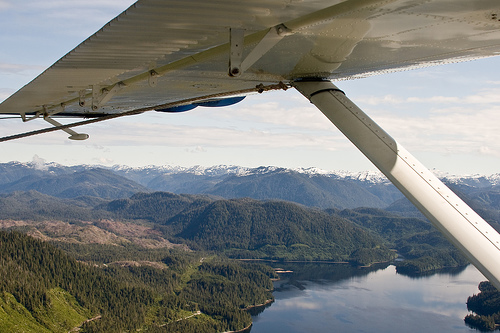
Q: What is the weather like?
A: It is clear.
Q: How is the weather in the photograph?
A: It is clear.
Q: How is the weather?
A: It is clear.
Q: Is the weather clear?
A: Yes, it is clear.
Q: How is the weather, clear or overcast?
A: It is clear.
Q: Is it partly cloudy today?
A: No, it is clear.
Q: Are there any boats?
A: No, there are no boats.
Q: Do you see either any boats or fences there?
A: No, there are no boats or fences.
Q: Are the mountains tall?
A: Yes, the mountains are tall.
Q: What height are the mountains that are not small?
A: The mountains are tall.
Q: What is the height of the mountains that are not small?
A: The mountains are tall.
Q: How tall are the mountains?
A: The mountains are tall.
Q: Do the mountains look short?
A: No, the mountains are tall.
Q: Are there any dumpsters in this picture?
A: No, there are no dumpsters.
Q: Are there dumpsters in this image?
A: No, there are no dumpsters.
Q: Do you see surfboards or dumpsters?
A: No, there are no dumpsters or surfboards.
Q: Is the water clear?
A: Yes, the water is clear.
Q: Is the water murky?
A: No, the water is clear.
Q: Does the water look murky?
A: No, the water is clear.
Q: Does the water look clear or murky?
A: The water is clear.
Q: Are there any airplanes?
A: Yes, there is an airplane.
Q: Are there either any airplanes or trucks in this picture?
A: Yes, there is an airplane.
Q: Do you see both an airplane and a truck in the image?
A: No, there is an airplane but no trucks.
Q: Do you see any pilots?
A: No, there are no pilots.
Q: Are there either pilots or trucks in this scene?
A: No, there are no pilots or trucks.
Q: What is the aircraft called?
A: The aircraft is an airplane.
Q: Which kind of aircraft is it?
A: The aircraft is an airplane.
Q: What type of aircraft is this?
A: This is an airplane.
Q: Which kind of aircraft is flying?
A: The aircraft is an airplane.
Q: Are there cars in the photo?
A: No, there are no cars.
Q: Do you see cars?
A: No, there are no cars.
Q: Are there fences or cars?
A: No, there are no cars or fences.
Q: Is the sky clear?
A: Yes, the sky is clear.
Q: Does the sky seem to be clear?
A: Yes, the sky is clear.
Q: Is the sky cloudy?
A: No, the sky is clear.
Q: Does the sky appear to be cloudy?
A: No, the sky is clear.